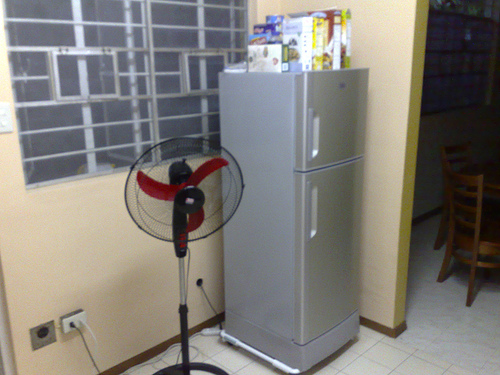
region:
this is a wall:
[41, 206, 83, 251]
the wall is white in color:
[32, 211, 102, 265]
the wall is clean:
[55, 236, 103, 268]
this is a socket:
[63, 310, 90, 329]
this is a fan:
[118, 121, 250, 369]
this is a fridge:
[229, 79, 366, 350]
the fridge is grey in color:
[258, 255, 294, 310]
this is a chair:
[441, 145, 483, 298]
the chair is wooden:
[447, 178, 469, 216]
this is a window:
[66, 108, 120, 158]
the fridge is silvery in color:
[262, 122, 348, 352]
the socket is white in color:
[56, 302, 93, 329]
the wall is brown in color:
[46, 250, 146, 302]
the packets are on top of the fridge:
[263, 15, 365, 72]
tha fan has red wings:
[155, 174, 225, 226]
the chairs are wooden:
[446, 164, 479, 271]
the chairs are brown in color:
[452, 180, 497, 278]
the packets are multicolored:
[255, 17, 357, 66]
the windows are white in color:
[56, 15, 163, 112]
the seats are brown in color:
[438, 165, 490, 260]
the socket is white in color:
[59, 315, 94, 329]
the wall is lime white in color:
[58, 207, 130, 279]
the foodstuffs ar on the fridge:
[248, 18, 370, 55]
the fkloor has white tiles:
[388, 308, 498, 374]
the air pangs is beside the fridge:
[117, 160, 239, 255]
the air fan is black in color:
[112, 135, 232, 241]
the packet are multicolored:
[253, 15, 364, 63]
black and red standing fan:
[120, 131, 254, 373]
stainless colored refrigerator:
[214, 60, 379, 372]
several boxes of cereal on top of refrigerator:
[229, 0, 362, 74]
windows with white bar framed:
[19, 6, 224, 151]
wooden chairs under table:
[430, 152, 498, 310]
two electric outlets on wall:
[19, 305, 96, 354]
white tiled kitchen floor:
[362, 336, 422, 373]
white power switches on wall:
[0, 90, 22, 137]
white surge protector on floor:
[196, 311, 232, 341]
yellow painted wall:
[66, 225, 97, 252]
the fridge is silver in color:
[222, 63, 369, 356]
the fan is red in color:
[135, 166, 226, 230]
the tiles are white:
[342, 341, 407, 373]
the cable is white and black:
[66, 312, 99, 347]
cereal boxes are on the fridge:
[259, 17, 360, 74]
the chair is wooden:
[438, 168, 498, 303]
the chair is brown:
[445, 169, 495, 309]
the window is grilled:
[17, 13, 233, 150]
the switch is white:
[2, 98, 20, 131]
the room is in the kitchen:
[16, 8, 498, 372]